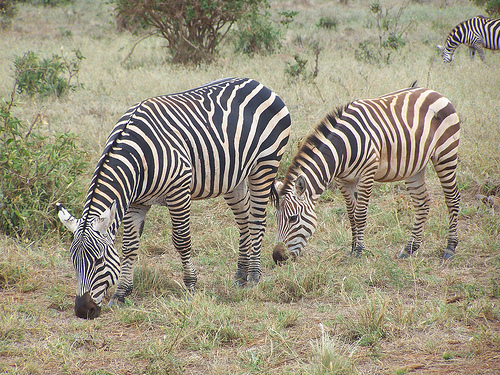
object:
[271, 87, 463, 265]
zebra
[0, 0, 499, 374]
grass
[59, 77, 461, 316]
zebras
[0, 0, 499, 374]
field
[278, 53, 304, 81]
bush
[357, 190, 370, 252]
leg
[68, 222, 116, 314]
face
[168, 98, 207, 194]
stripes